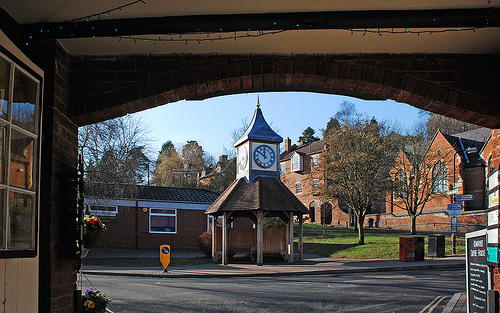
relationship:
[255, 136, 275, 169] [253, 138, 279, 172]
face on clock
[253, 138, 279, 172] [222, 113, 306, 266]
clock on gazebo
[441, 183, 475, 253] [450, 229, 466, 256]
signs on pole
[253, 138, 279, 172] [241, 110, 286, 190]
clock on tower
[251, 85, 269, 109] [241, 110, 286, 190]
spire on tower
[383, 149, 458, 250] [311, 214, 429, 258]
tree in grass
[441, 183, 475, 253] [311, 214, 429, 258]
signs in grass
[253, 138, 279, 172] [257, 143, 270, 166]
clock has numbers